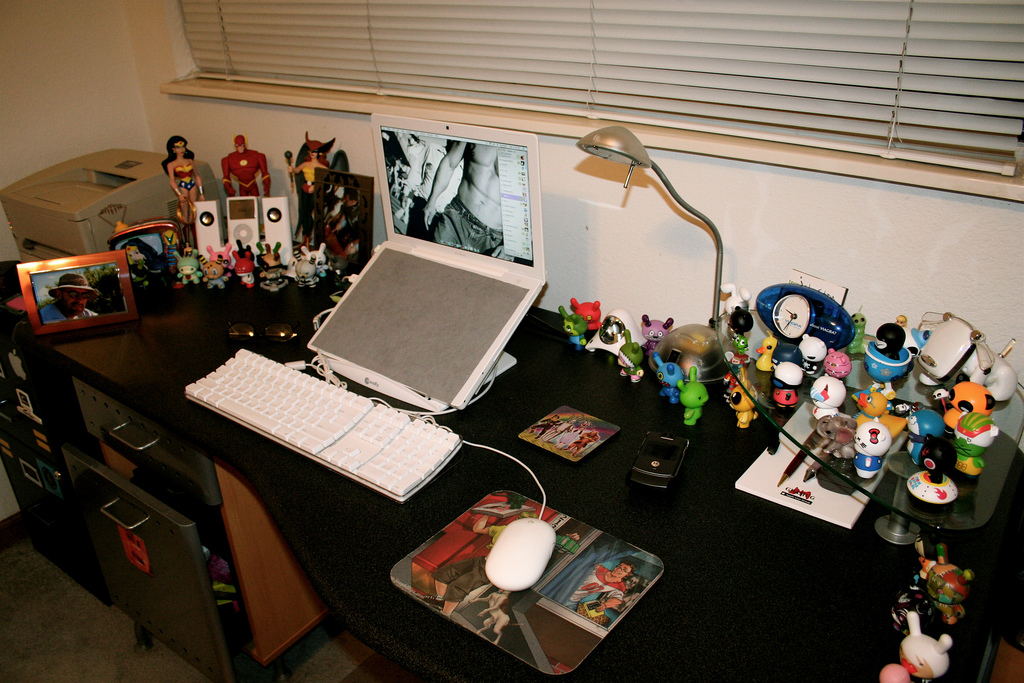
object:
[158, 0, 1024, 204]
blinds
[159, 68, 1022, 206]
ledge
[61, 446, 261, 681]
drawer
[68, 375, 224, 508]
drawer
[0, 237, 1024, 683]
desk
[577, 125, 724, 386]
lamp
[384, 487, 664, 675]
mousepad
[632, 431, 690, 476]
cellphone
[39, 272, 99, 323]
man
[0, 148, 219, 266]
printer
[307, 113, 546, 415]
computer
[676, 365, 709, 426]
action figure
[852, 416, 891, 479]
action figure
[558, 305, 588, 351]
action figure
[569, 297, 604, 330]
action figure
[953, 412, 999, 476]
action figure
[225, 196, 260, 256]
ipod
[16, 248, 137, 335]
frame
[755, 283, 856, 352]
clock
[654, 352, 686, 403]
figurine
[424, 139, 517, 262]
man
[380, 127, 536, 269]
screen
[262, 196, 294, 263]
speaker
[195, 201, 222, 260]
speaker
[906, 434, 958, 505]
figurine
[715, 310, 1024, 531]
shelf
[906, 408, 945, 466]
figurine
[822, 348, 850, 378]
figurine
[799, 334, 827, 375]
figurine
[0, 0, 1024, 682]
office space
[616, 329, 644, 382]
toy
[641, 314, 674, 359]
toy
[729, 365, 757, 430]
toy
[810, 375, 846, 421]
figurine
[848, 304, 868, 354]
figurine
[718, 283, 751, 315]
figurine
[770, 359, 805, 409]
figurine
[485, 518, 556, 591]
mouse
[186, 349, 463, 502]
keyboard